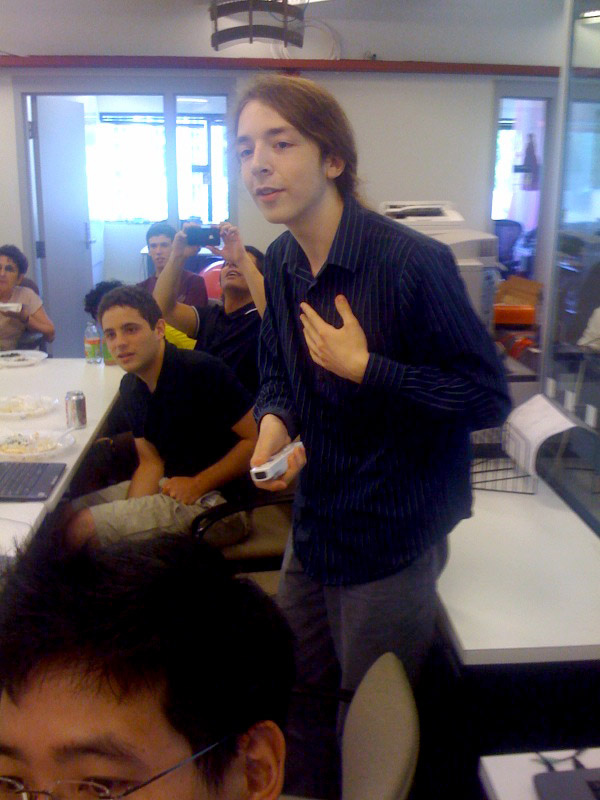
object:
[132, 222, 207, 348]
person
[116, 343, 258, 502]
clothing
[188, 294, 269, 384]
clothing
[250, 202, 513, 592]
clothing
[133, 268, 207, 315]
clothing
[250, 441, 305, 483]
controller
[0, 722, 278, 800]
glasses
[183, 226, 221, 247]
phone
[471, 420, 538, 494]
wirebasket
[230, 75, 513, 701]
man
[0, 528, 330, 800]
man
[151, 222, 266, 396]
man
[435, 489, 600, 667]
table